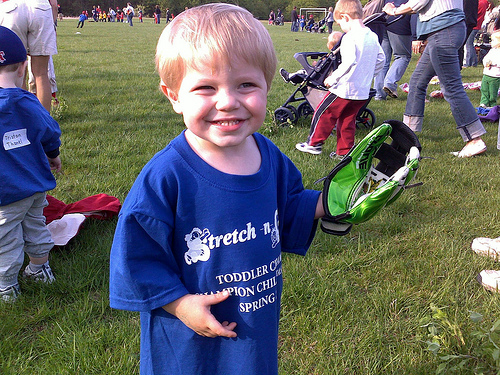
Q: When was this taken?
A: Day time.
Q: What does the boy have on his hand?
A: Baseball glove.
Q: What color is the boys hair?
A: Blonde.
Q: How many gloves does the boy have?
A: One.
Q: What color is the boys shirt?
A: Blue.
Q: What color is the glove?
A: Green.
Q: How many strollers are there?
A: One.